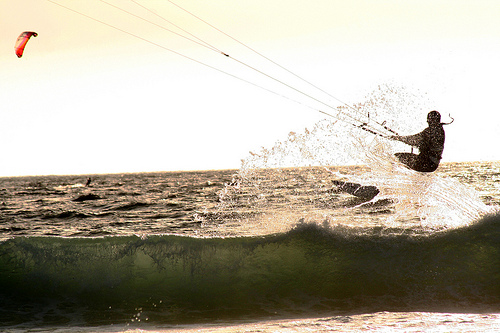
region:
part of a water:
[206, 260, 264, 301]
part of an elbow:
[391, 130, 423, 149]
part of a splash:
[281, 114, 348, 175]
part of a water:
[159, 166, 194, 196]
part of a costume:
[411, 150, 431, 170]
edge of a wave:
[271, 218, 335, 251]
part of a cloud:
[147, 100, 189, 148]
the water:
[117, 128, 289, 290]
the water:
[267, 146, 319, 262]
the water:
[262, 240, 294, 325]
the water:
[166, 169, 265, 311]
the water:
[191, 156, 310, 312]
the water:
[213, 235, 276, 318]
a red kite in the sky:
[6, 19, 47, 71]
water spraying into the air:
[269, 125, 311, 167]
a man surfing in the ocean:
[332, 72, 467, 238]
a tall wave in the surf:
[49, 221, 339, 268]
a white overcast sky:
[90, 65, 202, 151]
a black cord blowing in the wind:
[444, 112, 456, 128]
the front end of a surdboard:
[336, 175, 386, 201]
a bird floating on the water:
[79, 170, 94, 190]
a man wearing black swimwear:
[403, 98, 443, 188]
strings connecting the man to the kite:
[219, 30, 304, 99]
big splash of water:
[228, 134, 439, 276]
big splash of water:
[204, 105, 348, 282]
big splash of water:
[260, 125, 348, 215]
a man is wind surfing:
[297, 85, 452, 200]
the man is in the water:
[262, 87, 492, 263]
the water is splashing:
[165, 92, 442, 253]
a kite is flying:
[1, 18, 52, 78]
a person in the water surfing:
[37, 146, 127, 210]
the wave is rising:
[0, 209, 327, 319]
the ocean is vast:
[25, 85, 478, 313]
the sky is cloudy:
[52, 22, 369, 154]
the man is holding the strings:
[310, 72, 437, 179]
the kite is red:
[0, 7, 91, 119]